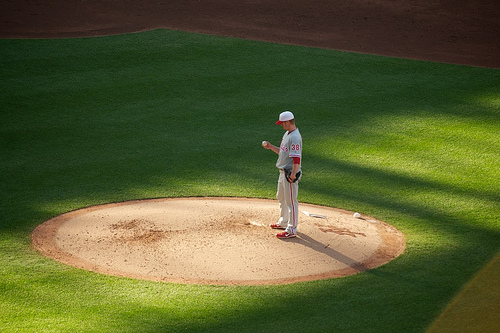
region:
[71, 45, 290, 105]
a beautiful green field.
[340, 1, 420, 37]
brown dirt in the field.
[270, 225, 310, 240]
a player is wearing red and white sneakers.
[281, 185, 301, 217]
a player is wearing red and white pants.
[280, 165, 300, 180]
a player is holding a black glove.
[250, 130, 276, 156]
a player is holding a white ball.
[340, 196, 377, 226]
a piece of white tissue.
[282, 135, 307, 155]
a player is number 38.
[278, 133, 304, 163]
a player is wearing a red and grey shirt.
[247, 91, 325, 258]
a player is going to throw the ball .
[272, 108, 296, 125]
the hat is white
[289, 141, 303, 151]
the number is red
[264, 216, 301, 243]
the shoes are red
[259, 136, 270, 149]
the ball is white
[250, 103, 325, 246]
the man is holding a ball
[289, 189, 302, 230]
the stripe is red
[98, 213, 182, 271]
the dirt is brown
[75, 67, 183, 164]
the field is manicured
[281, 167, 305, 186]
the man is wearing a glove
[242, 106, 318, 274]
the man is standing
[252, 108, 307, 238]
pitcher standing on mound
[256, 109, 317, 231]
pitcher holding baseball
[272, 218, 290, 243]
red cleats of pitcher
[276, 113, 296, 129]
white and red hat of pitcher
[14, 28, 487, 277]
shadows on grass field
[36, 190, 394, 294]
cirlce of dirt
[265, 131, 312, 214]
uniform of pitcher with red stripe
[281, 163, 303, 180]
black glove of pitcher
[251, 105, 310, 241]
player standing on baseball field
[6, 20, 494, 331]
infield and pitcher's mound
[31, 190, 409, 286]
Pitcher's mound on the field.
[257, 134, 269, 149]
Baseball in the hand.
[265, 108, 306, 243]
Man is wearing a baseball uniform.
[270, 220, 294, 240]
Red Nike shoes on the feet.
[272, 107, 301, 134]
Man is wearing a red and white cap.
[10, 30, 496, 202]
Green grass on the baseball field.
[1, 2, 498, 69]
Dirt on the edge of the grass.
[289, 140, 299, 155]
Red number 38 on the man's shirt.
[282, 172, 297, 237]
Red stripe down the pant leg.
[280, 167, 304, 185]
Black baseball glove on man's hand.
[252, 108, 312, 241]
player standing pitcher's mound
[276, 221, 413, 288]
player's shadow on field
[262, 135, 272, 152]
baseball player is holding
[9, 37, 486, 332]
shadows on infield grass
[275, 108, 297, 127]
white ball cap with red brim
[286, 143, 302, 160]
red number on player's sleeve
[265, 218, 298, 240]
red cleats of player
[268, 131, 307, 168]
jersery of baseball player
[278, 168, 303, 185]
black mitt of pitcher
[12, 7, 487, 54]
dirt of base path